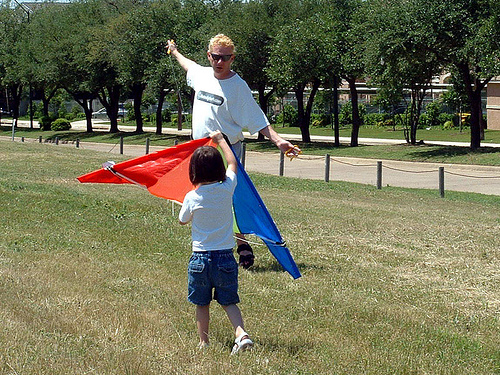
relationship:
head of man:
[186, 19, 262, 86] [114, 22, 340, 137]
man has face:
[114, 22, 340, 137] [202, 48, 242, 77]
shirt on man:
[172, 181, 269, 260] [114, 22, 340, 137]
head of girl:
[186, 19, 262, 86] [176, 140, 272, 373]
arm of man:
[242, 76, 312, 149] [114, 22, 340, 137]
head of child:
[186, 19, 262, 86] [137, 165, 270, 331]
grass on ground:
[2, 195, 103, 260] [64, 239, 164, 332]